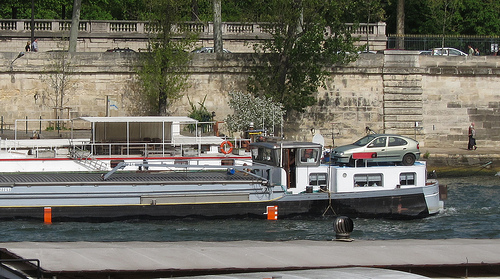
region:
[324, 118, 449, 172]
this is a car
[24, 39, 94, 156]
this is a tree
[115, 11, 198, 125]
this is a tree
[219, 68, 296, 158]
this is a tree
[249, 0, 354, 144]
this is a tree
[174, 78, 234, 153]
this is a tree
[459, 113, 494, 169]
this is a person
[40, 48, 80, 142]
this is a tree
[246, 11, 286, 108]
this is a tree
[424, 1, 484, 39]
this is a tree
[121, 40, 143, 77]
this is a branch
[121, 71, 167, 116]
this is a branch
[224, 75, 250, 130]
this is a branch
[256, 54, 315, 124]
this is a branch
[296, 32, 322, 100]
this is a branch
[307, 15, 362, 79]
this is a branch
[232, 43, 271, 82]
this is a branch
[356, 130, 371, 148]
window of a car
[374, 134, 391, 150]
window of a car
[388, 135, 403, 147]
window of a car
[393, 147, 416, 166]
tire of a car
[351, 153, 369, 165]
wheel of a car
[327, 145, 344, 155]
light of a car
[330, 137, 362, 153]
hood of a car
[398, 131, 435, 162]
back of a car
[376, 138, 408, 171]
door of a car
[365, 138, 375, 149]
mirror of a car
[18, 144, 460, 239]
this is a barge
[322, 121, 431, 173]
this is a car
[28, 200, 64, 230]
orange spot on barge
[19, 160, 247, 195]
black top on barge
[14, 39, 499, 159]
cement wall in background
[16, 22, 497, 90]
cars on top of wall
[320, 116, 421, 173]
the car is silver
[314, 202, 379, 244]
black bouey in water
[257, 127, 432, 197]
white top of barge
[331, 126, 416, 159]
a car on a boat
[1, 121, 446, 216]
a large white boat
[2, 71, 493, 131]
a stone wall behind the boat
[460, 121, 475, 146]
people walking next to the water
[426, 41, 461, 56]
a car on the street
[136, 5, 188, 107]
a tree in front of the wall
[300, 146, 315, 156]
a window on the boat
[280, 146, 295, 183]
a door on the boat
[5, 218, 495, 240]
water under the boat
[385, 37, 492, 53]
a fence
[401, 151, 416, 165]
Tire of a car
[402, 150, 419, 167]
Black tire of a car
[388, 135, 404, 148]
Window of a car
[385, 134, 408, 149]
Window of a car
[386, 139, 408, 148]
Window of a car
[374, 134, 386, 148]
Window of a car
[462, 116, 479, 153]
people walking on the siewalk